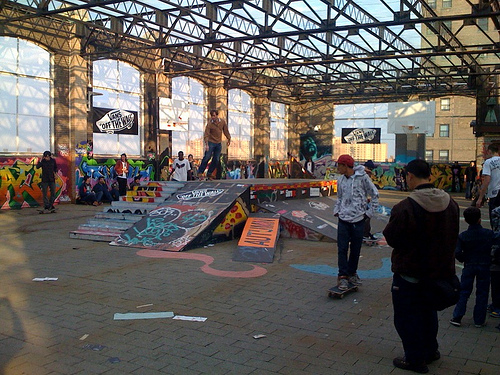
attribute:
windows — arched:
[0, 30, 295, 162]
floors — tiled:
[0, 179, 469, 372]